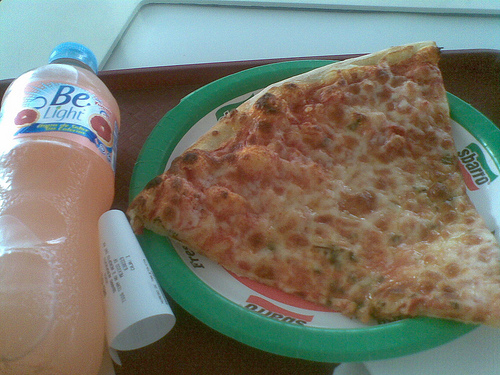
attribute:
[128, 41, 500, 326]
pizza — cheese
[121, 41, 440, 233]
crust — crisp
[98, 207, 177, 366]
receipt — rolled, white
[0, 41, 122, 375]
bottle — plastic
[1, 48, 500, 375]
tray — brown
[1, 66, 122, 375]
beverage — pink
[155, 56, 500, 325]
cheese — melted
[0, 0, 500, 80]
table — white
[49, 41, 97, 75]
cap — plastic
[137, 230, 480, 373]
rim — green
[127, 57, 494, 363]
plate — green, white